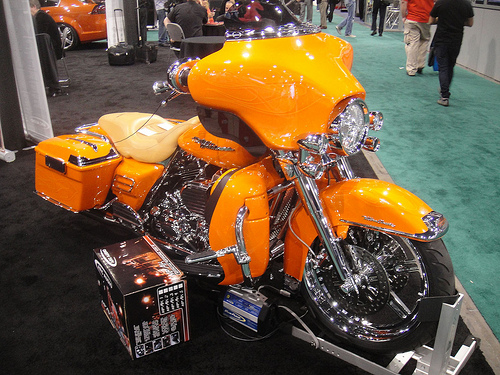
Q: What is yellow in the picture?
A: A motorcycle.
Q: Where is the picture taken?
A: An exhibition.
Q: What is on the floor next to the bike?
A: A box.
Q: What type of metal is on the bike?
A: Chrome.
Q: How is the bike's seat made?
A: Of leather.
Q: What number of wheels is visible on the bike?
A: One.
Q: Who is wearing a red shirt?
A: A male visitor.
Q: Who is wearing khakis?
A: A male visitor.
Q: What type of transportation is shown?
A: Motorcycle.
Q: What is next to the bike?
A: A box.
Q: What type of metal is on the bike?
A: Chrome.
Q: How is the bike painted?
A: In orange.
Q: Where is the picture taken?
A: An exhibition.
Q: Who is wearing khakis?
A: A man.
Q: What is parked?
A: A yellow motorcycle.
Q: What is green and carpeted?
A: The walkway.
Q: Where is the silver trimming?
A: On the motorcycle.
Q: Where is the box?
A: Beside the bike.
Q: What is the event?
A: A car show.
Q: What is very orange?
A: The bike.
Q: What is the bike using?
A: A stand.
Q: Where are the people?
A: On the carpet.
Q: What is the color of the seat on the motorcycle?
A: Beige.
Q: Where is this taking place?
A: Indoors under bright lights.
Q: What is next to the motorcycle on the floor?
A: A black box.